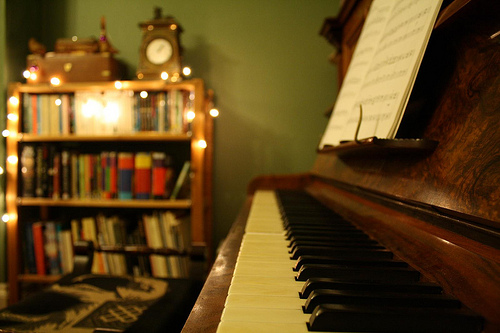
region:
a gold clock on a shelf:
[134, 0, 206, 95]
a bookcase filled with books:
[7, 87, 194, 281]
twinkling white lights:
[7, 82, 226, 147]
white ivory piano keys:
[237, 188, 278, 329]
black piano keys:
[285, 187, 367, 328]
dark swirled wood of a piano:
[437, 110, 464, 210]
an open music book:
[330, 102, 397, 129]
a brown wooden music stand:
[332, 133, 406, 150]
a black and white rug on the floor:
[26, 283, 151, 327]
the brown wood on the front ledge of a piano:
[191, 242, 228, 327]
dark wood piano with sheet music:
[176, 0, 499, 332]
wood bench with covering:
[1, 241, 208, 332]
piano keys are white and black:
[215, 186, 495, 331]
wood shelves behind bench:
[2, 80, 214, 306]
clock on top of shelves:
[136, 9, 182, 83]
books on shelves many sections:
[16, 90, 193, 280]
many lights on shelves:
[1, 64, 218, 221]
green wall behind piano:
[1, 1, 349, 280]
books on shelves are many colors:
[16, 90, 193, 279]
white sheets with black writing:
[321, 1, 443, 148]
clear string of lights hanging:
[6, 77, 21, 235]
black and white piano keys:
[261, 196, 311, 316]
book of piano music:
[322, 0, 439, 152]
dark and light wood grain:
[451, 82, 491, 211]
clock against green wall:
[135, 5, 187, 82]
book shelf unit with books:
[3, 10, 212, 277]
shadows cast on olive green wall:
[219, 36, 289, 163]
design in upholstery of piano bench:
[14, 270, 147, 332]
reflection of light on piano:
[415, 175, 477, 264]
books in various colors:
[68, 152, 170, 197]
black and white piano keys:
[222, 156, 478, 331]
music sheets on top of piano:
[298, 0, 467, 157]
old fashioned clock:
[125, 0, 194, 83]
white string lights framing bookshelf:
[0, 68, 233, 146]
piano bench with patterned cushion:
[5, 224, 229, 331]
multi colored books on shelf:
[19, 136, 203, 202]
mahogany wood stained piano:
[187, 4, 493, 331]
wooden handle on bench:
[73, 227, 205, 299]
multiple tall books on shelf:
[9, 198, 200, 283]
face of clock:
[138, 30, 174, 67]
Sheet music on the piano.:
[311, 0, 453, 162]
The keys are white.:
[243, 206, 284, 331]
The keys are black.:
[285, 195, 368, 322]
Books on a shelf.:
[22, 105, 173, 270]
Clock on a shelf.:
[132, 15, 192, 80]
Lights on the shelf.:
[3, 67, 211, 214]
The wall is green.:
[210, 20, 311, 132]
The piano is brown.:
[425, 77, 496, 192]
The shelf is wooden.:
[182, 160, 207, 233]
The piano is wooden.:
[375, 163, 486, 258]